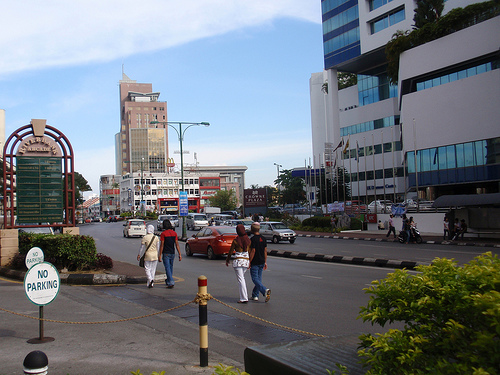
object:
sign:
[22, 258, 60, 345]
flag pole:
[370, 134, 378, 225]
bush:
[18, 229, 98, 270]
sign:
[0, 122, 79, 228]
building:
[114, 65, 170, 226]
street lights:
[148, 122, 210, 244]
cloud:
[0, 0, 320, 71]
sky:
[0, 1, 320, 178]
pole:
[195, 274, 212, 366]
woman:
[135, 221, 161, 287]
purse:
[136, 256, 145, 266]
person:
[156, 218, 183, 289]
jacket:
[159, 229, 177, 254]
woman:
[222, 224, 257, 303]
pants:
[232, 261, 251, 302]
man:
[244, 220, 270, 302]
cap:
[250, 221, 260, 229]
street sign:
[176, 190, 190, 217]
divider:
[258, 241, 464, 274]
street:
[0, 221, 498, 374]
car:
[183, 224, 242, 260]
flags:
[426, 145, 440, 167]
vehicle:
[121, 217, 153, 239]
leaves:
[64, 242, 75, 251]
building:
[308, 1, 499, 239]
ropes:
[205, 289, 335, 343]